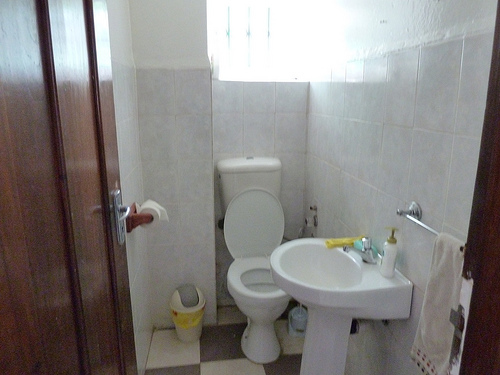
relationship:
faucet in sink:
[340, 234, 381, 262] [271, 232, 410, 320]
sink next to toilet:
[271, 232, 410, 320] [220, 186, 294, 362]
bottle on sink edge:
[379, 227, 398, 277] [321, 234, 407, 287]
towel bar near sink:
[395, 200, 438, 238] [271, 232, 410, 320]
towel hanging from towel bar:
[408, 235, 469, 370] [393, 201, 434, 238]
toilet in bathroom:
[215, 180, 311, 370] [83, 32, 482, 371]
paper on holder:
[139, 200, 166, 234] [123, 203, 152, 230]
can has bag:
[166, 284, 206, 344] [172, 308, 202, 328]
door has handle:
[3, 4, 145, 371] [110, 186, 130, 244]